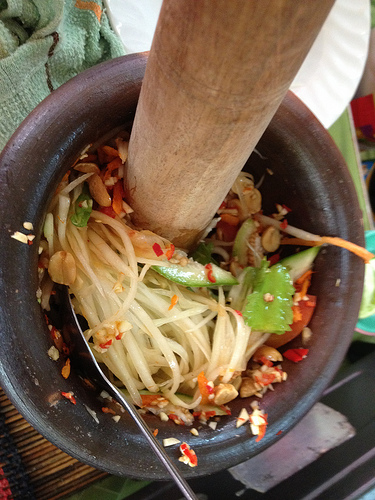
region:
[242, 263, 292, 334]
green cilantro leaf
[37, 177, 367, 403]
white sprouts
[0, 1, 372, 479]
grinding spices with a mortar and pestle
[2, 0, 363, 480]
grinding food ingredients with a mortar and pestle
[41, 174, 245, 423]
white bean sprouts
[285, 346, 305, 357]
hot red papper seed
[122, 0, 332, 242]
light colored pestle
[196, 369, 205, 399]
strip of orange grated carrot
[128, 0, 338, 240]
bamboo placemat with mortar and pestle on top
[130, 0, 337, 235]
marble pestle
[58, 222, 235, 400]
White noodles in bowl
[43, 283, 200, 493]
Silver utensil for eating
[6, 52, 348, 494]
Small brown cup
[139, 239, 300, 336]
Small pieces of green lettuce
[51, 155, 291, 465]
Small shredded pieces of food in cup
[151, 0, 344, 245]
Wooden post for mixing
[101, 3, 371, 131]
White paper plate in the distance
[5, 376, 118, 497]
Bamboo table under the cup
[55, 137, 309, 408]
Mixed food in cup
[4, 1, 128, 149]
Green and brown cloth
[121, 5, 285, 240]
A wooden stick in the bowl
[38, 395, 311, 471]
The bowl is the color black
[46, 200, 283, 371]
Different types of vegetables in the bowl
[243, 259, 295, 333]
The vegetable is the color green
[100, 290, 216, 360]
The vegetable is the color white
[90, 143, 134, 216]
The vegetable is the color orange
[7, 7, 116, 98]
A towel on the table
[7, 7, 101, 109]
The towel is the color green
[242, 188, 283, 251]
The peanuts in the bowl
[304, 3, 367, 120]
The plate is the color white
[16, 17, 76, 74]
the towel is green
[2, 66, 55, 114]
the towel is green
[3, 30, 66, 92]
the towel is green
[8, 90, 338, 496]
the bowl is brown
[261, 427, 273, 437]
part of a bowl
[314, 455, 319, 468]
part of a table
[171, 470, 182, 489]
part of a fork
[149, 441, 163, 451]
edge of a fork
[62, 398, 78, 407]
edge of a bowl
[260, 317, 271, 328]
part of a vegetable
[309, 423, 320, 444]
part of the table